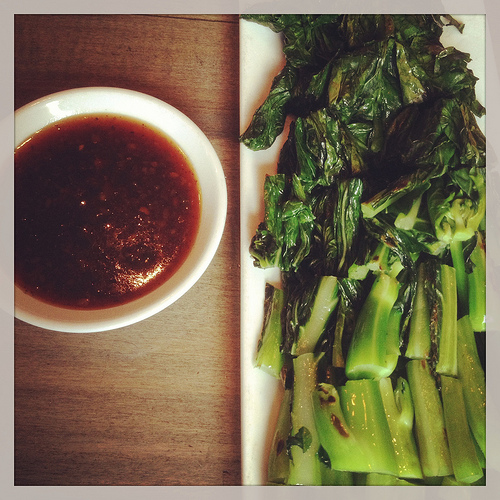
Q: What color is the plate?
A: White.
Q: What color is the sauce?
A: Red.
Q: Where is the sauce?
A: In the bowl.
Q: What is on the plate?
A: Spinach.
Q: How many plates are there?
A: One.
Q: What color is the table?
A: Brown.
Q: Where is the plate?
A: On the table.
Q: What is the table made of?
A: Wood.